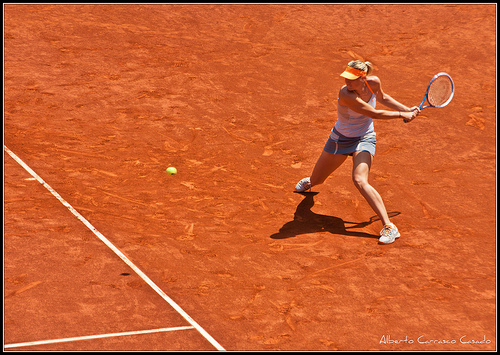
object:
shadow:
[270, 189, 379, 246]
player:
[293, 58, 421, 245]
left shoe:
[377, 225, 398, 244]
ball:
[165, 163, 178, 178]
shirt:
[333, 91, 380, 138]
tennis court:
[4, 4, 499, 354]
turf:
[8, 6, 495, 351]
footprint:
[183, 178, 203, 192]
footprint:
[177, 221, 197, 239]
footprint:
[263, 239, 281, 254]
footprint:
[210, 270, 232, 279]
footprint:
[381, 44, 391, 58]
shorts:
[321, 127, 376, 157]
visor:
[333, 67, 366, 83]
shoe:
[293, 174, 317, 194]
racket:
[403, 69, 456, 122]